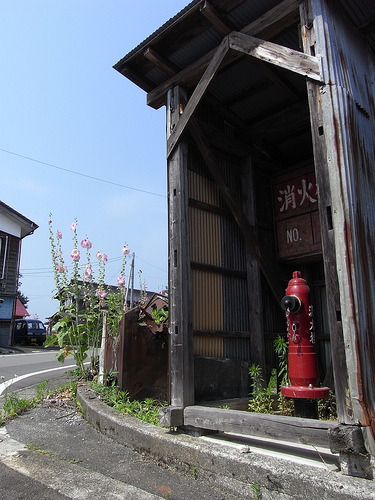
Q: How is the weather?
A: Clear.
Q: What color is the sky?
A: Blue.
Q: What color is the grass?
A: Green.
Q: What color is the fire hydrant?
A: Red.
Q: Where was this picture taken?
A: A shed.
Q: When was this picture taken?
A: Daytime.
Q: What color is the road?
A: Grey.